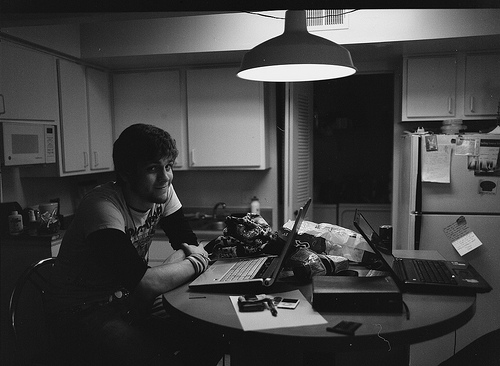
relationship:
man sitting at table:
[35, 118, 216, 359] [148, 234, 481, 355]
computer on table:
[182, 192, 319, 298] [148, 234, 481, 355]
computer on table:
[349, 205, 496, 299] [148, 234, 481, 355]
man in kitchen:
[51, 118, 210, 365] [2, 3, 492, 357]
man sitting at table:
[51, 118, 210, 365] [154, 246, 482, 363]